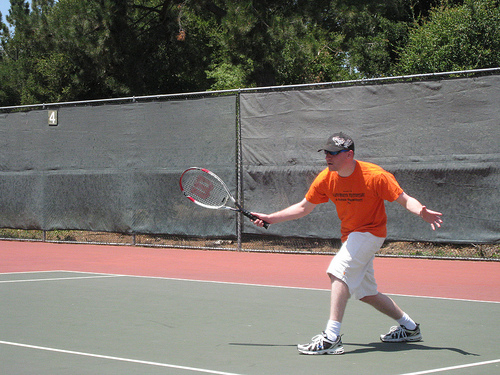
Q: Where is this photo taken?
A: On a tennis court.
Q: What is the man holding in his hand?
A: A tennis racket.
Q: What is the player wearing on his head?
A: A cap.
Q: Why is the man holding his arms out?
A: He is preparing to hit the tennis ball.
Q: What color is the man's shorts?
A: White.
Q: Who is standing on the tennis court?
A: A man.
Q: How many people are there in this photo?
A: One.